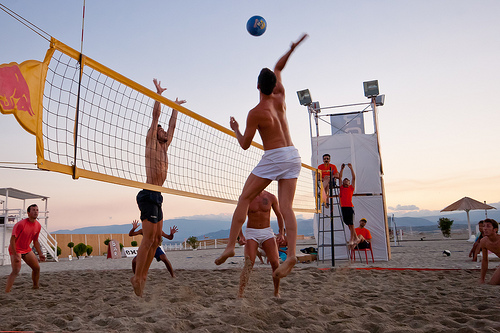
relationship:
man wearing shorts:
[213, 35, 311, 278] [251, 146, 304, 181]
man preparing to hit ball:
[213, 35, 311, 278] [246, 15, 268, 37]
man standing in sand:
[236, 188, 285, 298] [1, 232, 498, 332]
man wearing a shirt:
[337, 162, 359, 244] [338, 184, 355, 209]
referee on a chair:
[316, 153, 340, 206] [316, 183, 350, 265]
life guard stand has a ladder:
[1, 188, 61, 265] [36, 224, 58, 261]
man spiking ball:
[213, 35, 311, 278] [246, 15, 268, 37]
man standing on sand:
[4, 205, 46, 290] [1, 232, 498, 332]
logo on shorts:
[149, 215, 157, 220] [137, 186, 165, 223]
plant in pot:
[67, 242, 74, 256] [67, 254, 74, 260]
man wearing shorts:
[236, 188, 285, 298] [244, 226, 277, 244]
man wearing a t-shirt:
[4, 205, 46, 290] [6, 219, 41, 252]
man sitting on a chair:
[349, 218, 374, 251] [349, 242, 376, 264]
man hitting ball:
[213, 35, 311, 278] [246, 15, 268, 37]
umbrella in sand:
[442, 197, 497, 240] [1, 232, 498, 332]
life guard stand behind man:
[1, 188, 61, 265] [4, 205, 46, 290]